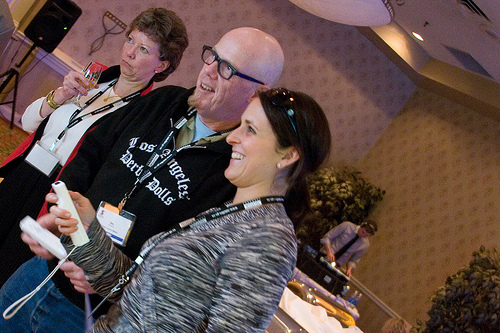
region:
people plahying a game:
[17, 12, 472, 299]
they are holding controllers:
[22, 162, 131, 314]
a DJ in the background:
[313, 197, 393, 319]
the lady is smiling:
[200, 81, 332, 211]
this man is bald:
[173, 22, 293, 108]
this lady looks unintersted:
[70, 18, 182, 86]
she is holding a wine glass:
[71, 58, 103, 110]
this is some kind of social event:
[86, 7, 434, 292]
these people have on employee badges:
[93, 184, 316, 291]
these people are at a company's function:
[53, 17, 338, 253]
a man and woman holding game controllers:
[1, 51, 347, 282]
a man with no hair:
[214, 23, 294, 81]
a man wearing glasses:
[190, 46, 260, 88]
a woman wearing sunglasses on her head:
[241, 83, 309, 140]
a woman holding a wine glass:
[70, 48, 126, 119]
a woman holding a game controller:
[50, 176, 105, 258]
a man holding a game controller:
[11, 204, 56, 292]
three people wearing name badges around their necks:
[0, 13, 280, 324]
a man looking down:
[343, 213, 387, 253]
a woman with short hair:
[104, 8, 192, 93]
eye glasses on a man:
[200, 41, 255, 96]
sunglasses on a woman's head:
[270, 75, 305, 156]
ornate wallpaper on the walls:
[414, 128, 498, 223]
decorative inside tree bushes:
[422, 231, 497, 329]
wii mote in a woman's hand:
[46, 167, 92, 260]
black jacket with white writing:
[107, 110, 213, 251]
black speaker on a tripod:
[25, 0, 75, 53]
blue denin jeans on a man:
[10, 260, 57, 330]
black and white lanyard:
[195, 193, 295, 234]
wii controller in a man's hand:
[21, 214, 63, 279]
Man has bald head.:
[238, 18, 289, 94]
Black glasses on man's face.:
[191, 33, 260, 103]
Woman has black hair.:
[272, 87, 319, 200]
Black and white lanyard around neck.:
[168, 207, 278, 242]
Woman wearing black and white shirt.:
[178, 235, 256, 306]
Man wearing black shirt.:
[106, 129, 183, 201]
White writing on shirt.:
[131, 129, 193, 231]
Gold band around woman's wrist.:
[46, 84, 73, 119]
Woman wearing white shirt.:
[57, 123, 79, 150]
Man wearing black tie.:
[333, 222, 370, 276]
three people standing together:
[13, 10, 351, 330]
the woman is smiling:
[226, 85, 323, 220]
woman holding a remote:
[18, 172, 142, 297]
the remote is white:
[44, 178, 98, 250]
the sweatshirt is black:
[46, 85, 266, 261]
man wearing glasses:
[195, 35, 266, 110]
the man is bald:
[163, 20, 303, 142]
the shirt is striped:
[155, 228, 299, 313]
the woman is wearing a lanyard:
[96, 170, 333, 307]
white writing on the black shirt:
[70, 89, 297, 264]